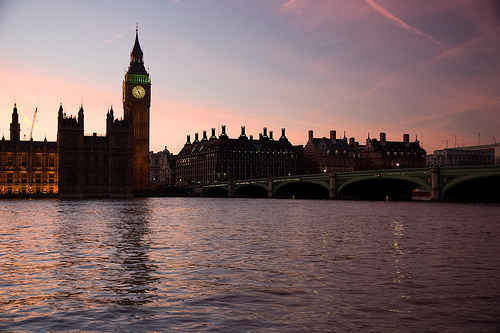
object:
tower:
[121, 25, 150, 190]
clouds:
[305, 0, 500, 119]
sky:
[152, 0, 500, 98]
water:
[0, 199, 500, 332]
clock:
[131, 85, 147, 99]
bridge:
[183, 163, 496, 205]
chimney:
[185, 134, 191, 146]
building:
[174, 124, 296, 185]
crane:
[28, 107, 39, 141]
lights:
[214, 162, 402, 176]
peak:
[134, 21, 140, 43]